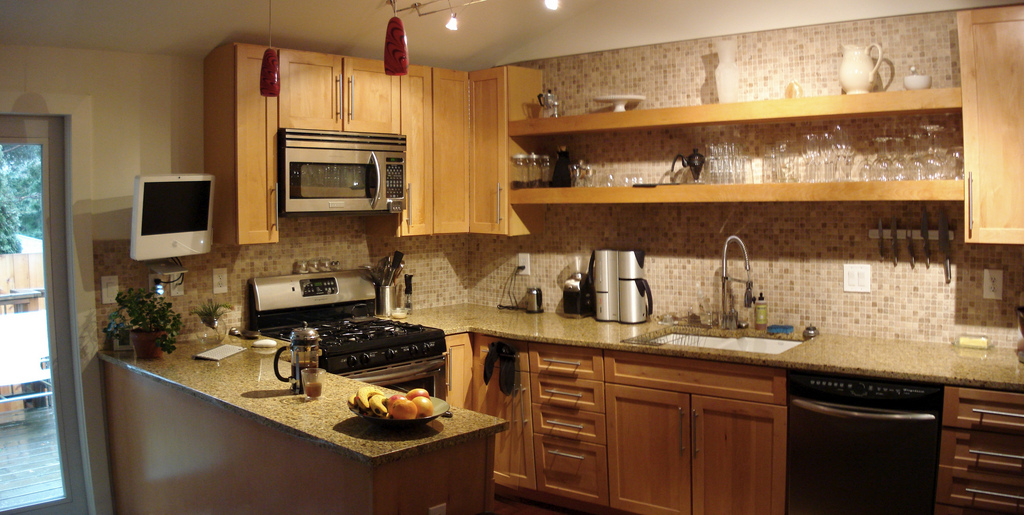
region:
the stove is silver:
[240, 249, 463, 406]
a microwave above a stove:
[267, 112, 441, 391]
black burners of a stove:
[301, 305, 444, 364]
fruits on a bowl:
[329, 359, 460, 436]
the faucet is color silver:
[710, 213, 753, 341]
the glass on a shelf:
[877, 128, 909, 183]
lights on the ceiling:
[429, 0, 588, 49]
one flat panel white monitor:
[122, 163, 220, 268]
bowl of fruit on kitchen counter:
[344, 380, 474, 441]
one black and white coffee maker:
[588, 244, 655, 328]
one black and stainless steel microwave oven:
[278, 125, 415, 218]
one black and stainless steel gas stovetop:
[239, 261, 454, 370]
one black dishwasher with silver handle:
[784, 353, 949, 508]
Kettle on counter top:
[587, 237, 655, 330]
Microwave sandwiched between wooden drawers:
[275, 121, 424, 227]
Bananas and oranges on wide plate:
[332, 383, 450, 429]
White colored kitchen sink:
[661, 320, 786, 353]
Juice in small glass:
[294, 358, 329, 401]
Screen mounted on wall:
[120, 155, 226, 270]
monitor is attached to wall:
[125, 168, 218, 263]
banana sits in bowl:
[353, 379, 376, 412]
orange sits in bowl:
[390, 393, 419, 426]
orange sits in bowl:
[413, 393, 432, 416]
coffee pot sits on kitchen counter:
[589, 241, 657, 330]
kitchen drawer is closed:
[533, 343, 607, 386]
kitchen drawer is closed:
[527, 367, 608, 416]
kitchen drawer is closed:
[529, 400, 609, 446]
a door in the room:
[4, 125, 65, 502]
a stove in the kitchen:
[266, 266, 422, 387]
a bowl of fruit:
[340, 383, 443, 419]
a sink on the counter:
[677, 238, 788, 357]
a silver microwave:
[280, 130, 401, 211]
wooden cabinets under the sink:
[487, 351, 770, 507]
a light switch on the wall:
[838, 263, 868, 289]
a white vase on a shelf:
[835, 39, 880, 82]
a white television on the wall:
[131, 172, 209, 256]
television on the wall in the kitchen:
[92, 151, 226, 292]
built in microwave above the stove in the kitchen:
[280, 116, 420, 228]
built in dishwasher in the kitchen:
[779, 360, 956, 513]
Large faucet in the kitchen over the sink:
[656, 231, 790, 372]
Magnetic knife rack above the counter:
[830, 206, 1002, 306]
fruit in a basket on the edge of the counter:
[340, 367, 467, 459]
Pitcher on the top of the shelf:
[819, 28, 887, 111]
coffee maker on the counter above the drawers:
[550, 230, 696, 361]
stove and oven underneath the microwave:
[241, 228, 530, 513]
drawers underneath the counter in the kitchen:
[517, 325, 644, 507]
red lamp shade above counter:
[374, 11, 413, 76]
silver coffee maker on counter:
[579, 238, 662, 337]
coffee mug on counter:
[272, 314, 326, 398]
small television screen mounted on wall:
[112, 160, 221, 271]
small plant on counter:
[102, 281, 182, 361]